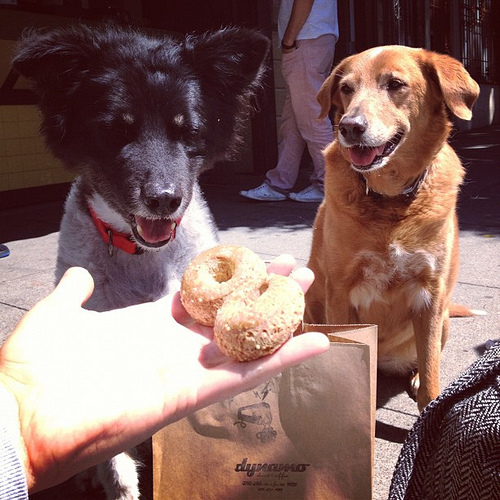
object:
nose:
[147, 193, 181, 214]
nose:
[338, 120, 364, 141]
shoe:
[288, 185, 325, 202]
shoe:
[241, 184, 288, 201]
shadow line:
[0, 135, 498, 246]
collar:
[85, 201, 144, 256]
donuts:
[176, 241, 265, 327]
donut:
[215, 273, 307, 363]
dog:
[300, 44, 485, 412]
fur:
[318, 147, 463, 389]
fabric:
[386, 340, 500, 500]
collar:
[361, 170, 427, 203]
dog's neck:
[346, 146, 448, 193]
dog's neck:
[73, 185, 162, 255]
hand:
[0, 249, 330, 486]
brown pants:
[265, 32, 339, 194]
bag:
[150, 322, 379, 500]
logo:
[233, 382, 278, 445]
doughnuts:
[214, 270, 305, 361]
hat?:
[387, 342, 500, 500]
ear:
[317, 56, 350, 121]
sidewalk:
[2, 130, 500, 500]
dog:
[0, 0, 229, 500]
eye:
[382, 79, 405, 92]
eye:
[339, 82, 353, 95]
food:
[179, 241, 307, 364]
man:
[238, 0, 336, 202]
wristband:
[282, 42, 297, 49]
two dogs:
[0, 23, 484, 412]